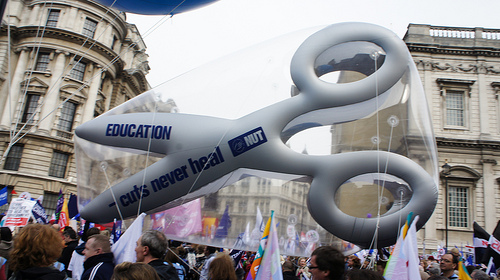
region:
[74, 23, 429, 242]
Balloon scissors in the air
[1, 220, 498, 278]
People in the street demonstrating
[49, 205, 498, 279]
People lifting flags in air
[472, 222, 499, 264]
Black and white flags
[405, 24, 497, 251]
Building made of stones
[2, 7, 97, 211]
Ten windows on a building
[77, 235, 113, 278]
Man wearing black jacket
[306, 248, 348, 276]
Man wearing sunglasses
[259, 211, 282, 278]
White flag in the air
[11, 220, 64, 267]
Woman with blonde hair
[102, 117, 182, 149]
The word Education on the blade of the scissor.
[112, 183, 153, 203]
The word Cuts on the blade of the scissor.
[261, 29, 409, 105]
The left handle of the scissor.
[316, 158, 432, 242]
The right handle of the scissor.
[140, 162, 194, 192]
The word Never on the blade of the scissor.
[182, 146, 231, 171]
The word Heal on the blade of the scissor.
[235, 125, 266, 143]
The word Nut on the blade of the scissor.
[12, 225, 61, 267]
The lady's red hair on the left.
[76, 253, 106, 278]
The black jacket with white stripes the man is wearing.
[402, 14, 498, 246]
The building on the right.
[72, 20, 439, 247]
giant gray inflatable scissors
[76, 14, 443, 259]
scissors are in a clear plastic bag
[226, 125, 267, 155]
blue rectangular logo on scissors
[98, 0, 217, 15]
blue balloon above scissors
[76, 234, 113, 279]
person wearing a black jacket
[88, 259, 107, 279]
white stripe on black jacket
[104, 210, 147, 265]
white flag in front of scissors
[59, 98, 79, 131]
window on building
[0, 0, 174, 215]
building to the left of scissors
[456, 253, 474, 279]
blue and yellow flag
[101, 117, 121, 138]
The blue letter E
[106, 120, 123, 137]
the blue letter D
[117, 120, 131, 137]
the blue letter U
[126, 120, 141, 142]
the blue letter C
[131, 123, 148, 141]
the blue letter A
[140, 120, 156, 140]
the blue letter T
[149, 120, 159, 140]
the blue letter I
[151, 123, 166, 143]
the blue letter O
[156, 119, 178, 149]
the blue letter N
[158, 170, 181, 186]
the blue letter V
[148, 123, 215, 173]
An inflatable pair of scissors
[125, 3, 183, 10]
A portion of a blue balloon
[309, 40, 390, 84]
Oval transparent shape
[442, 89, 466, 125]
A window in a building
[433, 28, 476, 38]
A parapet on the roof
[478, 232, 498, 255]
Black and white flags with some red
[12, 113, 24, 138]
Strings attached to a balloon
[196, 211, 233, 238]
Flags seen through polythene paper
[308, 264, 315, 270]
Dark shades in the face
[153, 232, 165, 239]
Balding in the crown of the head